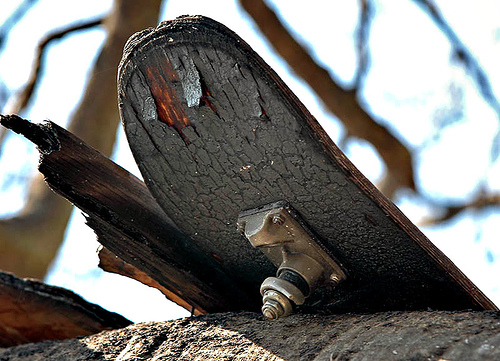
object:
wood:
[0, 308, 497, 361]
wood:
[0, 114, 244, 314]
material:
[2, 309, 499, 361]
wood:
[114, 14, 498, 315]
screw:
[260, 270, 306, 320]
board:
[115, 13, 500, 321]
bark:
[97, 244, 203, 316]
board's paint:
[115, 12, 498, 310]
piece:
[377, 335, 400, 352]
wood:
[0, 270, 136, 347]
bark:
[1, 309, 498, 361]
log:
[1, 311, 500, 361]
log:
[0, 114, 229, 314]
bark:
[0, 268, 136, 346]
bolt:
[329, 272, 342, 286]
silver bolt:
[272, 214, 285, 227]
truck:
[236, 198, 348, 322]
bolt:
[236, 222, 245, 235]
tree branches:
[0, 0, 499, 229]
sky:
[0, 0, 500, 320]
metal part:
[235, 199, 348, 323]